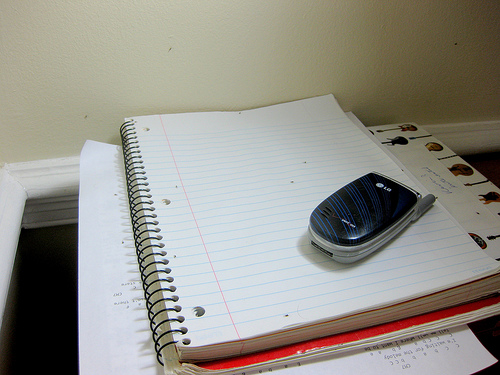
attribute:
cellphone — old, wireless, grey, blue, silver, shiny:
[314, 166, 416, 253]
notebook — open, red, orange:
[114, 110, 472, 341]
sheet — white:
[78, 151, 146, 363]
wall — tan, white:
[55, 16, 494, 106]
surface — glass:
[23, 204, 76, 364]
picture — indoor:
[34, 23, 496, 296]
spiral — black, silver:
[113, 126, 157, 283]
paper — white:
[59, 148, 154, 375]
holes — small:
[147, 118, 169, 226]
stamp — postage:
[467, 215, 500, 275]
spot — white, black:
[83, 346, 99, 375]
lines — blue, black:
[344, 191, 380, 220]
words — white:
[333, 217, 359, 236]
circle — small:
[377, 178, 387, 189]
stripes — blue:
[334, 202, 390, 233]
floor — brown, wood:
[464, 150, 499, 175]